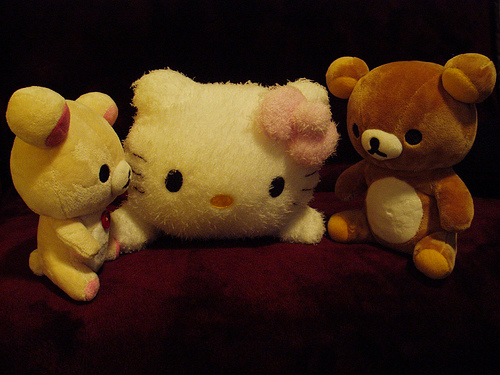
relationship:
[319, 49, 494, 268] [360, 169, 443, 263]
animals has belly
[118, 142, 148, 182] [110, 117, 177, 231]
whiskers on cheek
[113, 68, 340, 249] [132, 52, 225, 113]
cat has ears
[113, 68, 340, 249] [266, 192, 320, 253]
cat has feet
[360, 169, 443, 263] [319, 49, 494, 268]
belly of animals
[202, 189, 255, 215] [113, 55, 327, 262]
nose on cat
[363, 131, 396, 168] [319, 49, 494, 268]
nose on animals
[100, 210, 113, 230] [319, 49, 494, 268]
button on animals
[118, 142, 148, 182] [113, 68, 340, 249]
whiskers on cat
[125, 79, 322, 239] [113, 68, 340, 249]
head belonging to cat